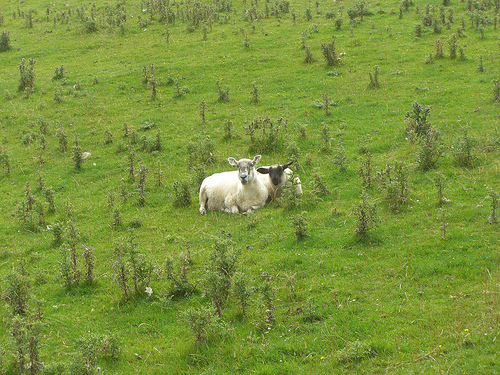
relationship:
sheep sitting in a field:
[194, 157, 267, 216] [2, 4, 500, 371]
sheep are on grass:
[194, 157, 267, 216] [3, 3, 500, 375]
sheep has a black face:
[258, 161, 303, 195] [256, 165, 290, 184]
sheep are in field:
[194, 157, 267, 216] [2, 4, 500, 371]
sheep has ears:
[194, 157, 267, 216] [225, 155, 263, 165]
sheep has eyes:
[194, 157, 267, 216] [227, 151, 261, 171]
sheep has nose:
[194, 157, 267, 216] [239, 172, 250, 183]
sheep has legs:
[194, 157, 267, 216] [196, 197, 247, 218]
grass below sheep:
[3, 3, 500, 375] [194, 157, 267, 216]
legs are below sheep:
[196, 197, 247, 218] [194, 157, 267, 216]